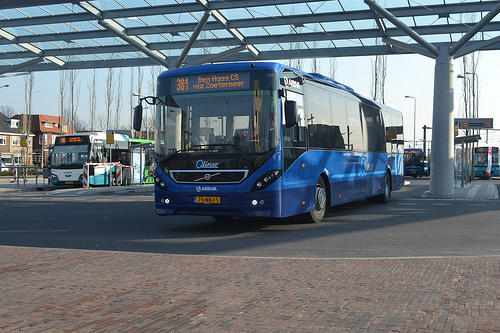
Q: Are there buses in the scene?
A: Yes, there is a bus.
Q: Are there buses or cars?
A: Yes, there is a bus.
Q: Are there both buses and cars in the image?
A: No, there is a bus but no cars.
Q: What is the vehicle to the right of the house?
A: The vehicle is a bus.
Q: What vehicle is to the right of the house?
A: The vehicle is a bus.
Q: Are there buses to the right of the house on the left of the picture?
A: Yes, there is a bus to the right of the house.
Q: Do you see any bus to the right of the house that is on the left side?
A: Yes, there is a bus to the right of the house.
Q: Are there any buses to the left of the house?
A: No, the bus is to the right of the house.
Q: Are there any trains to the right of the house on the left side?
A: No, there is a bus to the right of the house.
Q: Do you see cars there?
A: No, there are no cars.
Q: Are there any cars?
A: No, there are no cars.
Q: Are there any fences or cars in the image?
A: No, there are no cars or fences.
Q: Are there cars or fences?
A: No, there are no cars or fences.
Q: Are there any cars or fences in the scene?
A: No, there are no cars or fences.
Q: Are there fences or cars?
A: No, there are no cars or fences.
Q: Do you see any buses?
A: Yes, there is a bus.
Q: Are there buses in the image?
A: Yes, there is a bus.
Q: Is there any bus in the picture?
A: Yes, there is a bus.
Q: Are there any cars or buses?
A: Yes, there is a bus.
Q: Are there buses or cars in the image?
A: Yes, there is a bus.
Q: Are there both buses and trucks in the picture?
A: No, there is a bus but no trucks.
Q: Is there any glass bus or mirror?
A: Yes, there is a glass bus.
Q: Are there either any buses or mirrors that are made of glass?
A: Yes, the bus is made of glass.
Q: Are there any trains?
A: No, there are no trains.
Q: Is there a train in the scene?
A: No, there are no trains.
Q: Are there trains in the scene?
A: No, there are no trains.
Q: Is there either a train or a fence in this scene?
A: No, there are no trains or fences.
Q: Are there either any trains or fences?
A: No, there are no trains or fences.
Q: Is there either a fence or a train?
A: No, there are no trains or fences.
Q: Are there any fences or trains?
A: No, there are no trains or fences.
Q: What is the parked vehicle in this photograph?
A: The vehicle is a bus.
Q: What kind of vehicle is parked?
A: The vehicle is a bus.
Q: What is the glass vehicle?
A: The vehicle is a bus.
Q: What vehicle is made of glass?
A: The vehicle is a bus.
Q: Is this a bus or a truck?
A: This is a bus.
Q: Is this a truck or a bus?
A: This is a bus.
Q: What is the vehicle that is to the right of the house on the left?
A: The vehicle is a bus.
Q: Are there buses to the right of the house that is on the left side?
A: Yes, there is a bus to the right of the house.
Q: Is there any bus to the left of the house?
A: No, the bus is to the right of the house.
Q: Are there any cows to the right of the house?
A: No, there is a bus to the right of the house.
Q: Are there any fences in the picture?
A: No, there are no fences.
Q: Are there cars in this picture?
A: No, there are no cars.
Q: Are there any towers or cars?
A: No, there are no cars or towers.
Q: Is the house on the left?
A: Yes, the house is on the left of the image.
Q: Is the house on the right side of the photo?
A: No, the house is on the left of the image.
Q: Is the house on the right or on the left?
A: The house is on the left of the image.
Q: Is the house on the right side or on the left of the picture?
A: The house is on the left of the image.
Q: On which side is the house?
A: The house is on the left of the image.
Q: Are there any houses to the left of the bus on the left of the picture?
A: Yes, there is a house to the left of the bus.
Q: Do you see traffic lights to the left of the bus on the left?
A: No, there is a house to the left of the bus.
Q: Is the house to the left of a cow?
A: No, the house is to the left of the bus.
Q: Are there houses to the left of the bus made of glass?
A: Yes, there is a house to the left of the bus.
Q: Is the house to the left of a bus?
A: Yes, the house is to the left of a bus.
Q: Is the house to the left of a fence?
A: No, the house is to the left of a bus.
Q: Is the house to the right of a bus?
A: No, the house is to the left of a bus.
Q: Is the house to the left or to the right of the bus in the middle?
A: The house is to the left of the bus.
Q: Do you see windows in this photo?
A: Yes, there is a window.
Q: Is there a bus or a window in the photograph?
A: Yes, there is a window.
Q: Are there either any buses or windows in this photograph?
A: Yes, there is a window.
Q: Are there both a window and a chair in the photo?
A: No, there is a window but no chairs.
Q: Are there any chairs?
A: No, there are no chairs.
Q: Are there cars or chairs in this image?
A: No, there are no chairs or cars.